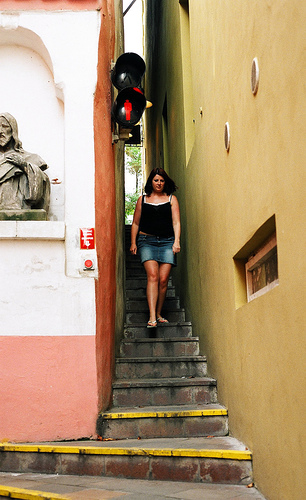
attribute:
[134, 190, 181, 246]
shirt — black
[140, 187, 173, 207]
border — white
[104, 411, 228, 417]
edge — yellow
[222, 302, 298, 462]
wall — brown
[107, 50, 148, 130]
sign — black, traffic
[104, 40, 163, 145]
lamp — lighted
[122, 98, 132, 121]
person outline — red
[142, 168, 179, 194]
hair — long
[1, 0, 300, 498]
building — wall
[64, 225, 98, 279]
red sign — wall, white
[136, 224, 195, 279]
skirt — small, blue, jean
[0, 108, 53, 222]
figure — stone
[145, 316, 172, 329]
sandals — white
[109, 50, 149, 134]
light — red, pedestrian, traffic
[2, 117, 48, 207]
statue — silver, wall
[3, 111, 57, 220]
statue — Jesus, wall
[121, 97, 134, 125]
man logo — red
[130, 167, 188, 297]
lady — light skinned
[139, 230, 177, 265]
skirt — jean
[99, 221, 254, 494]
staircase — narrow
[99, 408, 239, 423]
edge — yellow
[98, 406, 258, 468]
edge — yellow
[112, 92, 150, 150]
light — traffic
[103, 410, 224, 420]
edges — yellow